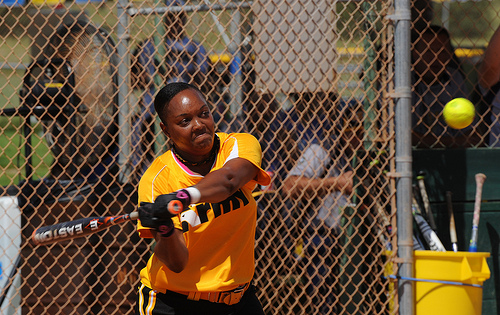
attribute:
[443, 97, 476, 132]
ball — green, chartreuse, flying, yellow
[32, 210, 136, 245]
bat — black, swinging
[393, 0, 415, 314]
pole — gray, tall, metal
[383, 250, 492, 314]
bucket — yellow, large, plastic, full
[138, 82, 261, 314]
girl — yellow, swinging, shirt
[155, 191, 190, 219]
glove — black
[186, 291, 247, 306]
belt — yellow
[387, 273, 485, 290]
rope — blue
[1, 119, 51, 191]
grass — green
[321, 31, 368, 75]
fence — wire, chain, behind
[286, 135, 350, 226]
shirt — gray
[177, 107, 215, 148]
face — determined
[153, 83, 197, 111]
hair — black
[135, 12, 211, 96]
people — watching